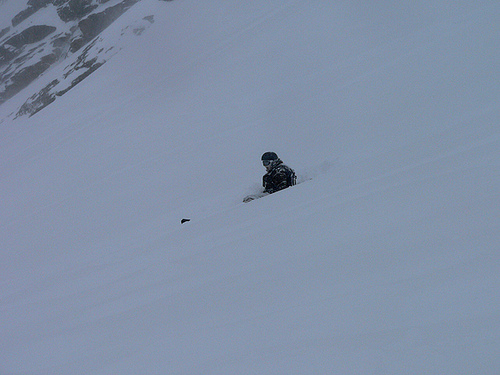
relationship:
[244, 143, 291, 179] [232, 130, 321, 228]
hat of a person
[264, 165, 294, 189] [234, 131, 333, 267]
jacket of a person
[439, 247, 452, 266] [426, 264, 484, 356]
part of a white surface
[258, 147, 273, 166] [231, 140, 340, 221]
head of man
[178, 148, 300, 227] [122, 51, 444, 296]
man in snow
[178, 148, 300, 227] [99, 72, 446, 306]
man surrounded by snow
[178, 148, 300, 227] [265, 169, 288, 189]
man wearing black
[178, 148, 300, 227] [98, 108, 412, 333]
man down in snow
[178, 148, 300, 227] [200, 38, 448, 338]
man covered in snow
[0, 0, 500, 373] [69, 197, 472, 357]
snow on ground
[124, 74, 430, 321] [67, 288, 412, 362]
snow on ground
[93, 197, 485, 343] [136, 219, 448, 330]
ground covered in snow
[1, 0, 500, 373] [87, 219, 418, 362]
ground covered in snow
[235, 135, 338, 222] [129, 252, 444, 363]
man covered in snow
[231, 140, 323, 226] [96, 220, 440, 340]
man covered in snow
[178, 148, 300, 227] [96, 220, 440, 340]
man covered with snow